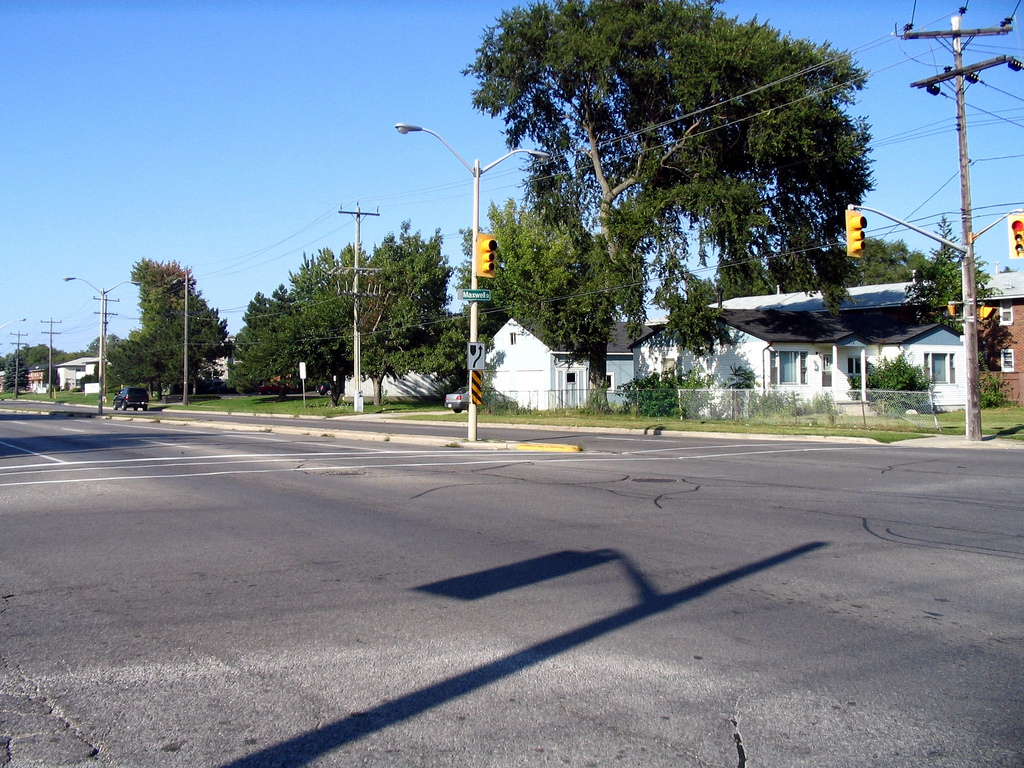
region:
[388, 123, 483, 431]
Street lamp attached to pole.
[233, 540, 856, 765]
Shadow cast on the ground.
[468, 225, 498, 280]
Yellow traffic signal light.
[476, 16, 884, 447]
Large tree with branches over house.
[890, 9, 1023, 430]
Electrical pole with wires.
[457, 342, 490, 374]
Black and white traffic sign.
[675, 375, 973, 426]
A low, metal fence.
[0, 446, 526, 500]
White lines marking crosswalk.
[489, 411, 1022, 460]
Concrete curb on side of street.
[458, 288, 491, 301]
Green and white street sign.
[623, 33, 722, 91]
the leaves are green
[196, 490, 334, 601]
the street is grey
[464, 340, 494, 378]
a white sign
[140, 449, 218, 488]
white lines in the street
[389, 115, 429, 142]
a street light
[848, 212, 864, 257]
a traffic light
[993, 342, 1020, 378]
a small window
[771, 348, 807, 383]
a window on the house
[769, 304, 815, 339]
the rooftop on the house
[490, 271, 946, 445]
white house with black roof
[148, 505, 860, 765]
shadow is on the road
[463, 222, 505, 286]
the traffic light on a pole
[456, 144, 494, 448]
the pole is color silver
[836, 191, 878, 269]
the traffic light on a pole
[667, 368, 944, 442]
fence on front a house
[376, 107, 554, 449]
a pole holding two light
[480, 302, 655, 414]
the house has a black roof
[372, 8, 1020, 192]
the pole holding wires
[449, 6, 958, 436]
the tree on front the house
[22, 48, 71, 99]
white clouds in blue sky